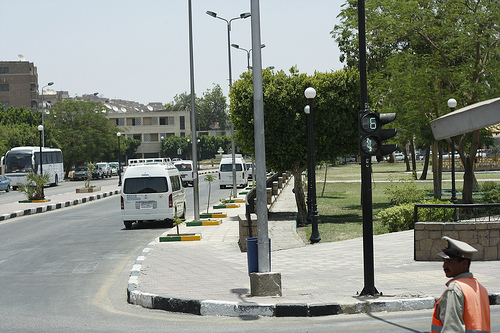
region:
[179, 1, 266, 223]
Series of street lamps along road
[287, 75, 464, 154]
White and black street lamps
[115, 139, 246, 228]
Three white vans driving on road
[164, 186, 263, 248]
Small trees with green and yellow planters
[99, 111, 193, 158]
Beige office building surrounded by bushes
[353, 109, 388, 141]
Number 6 on crosswalk light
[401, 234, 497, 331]
Crossing guard with orange vest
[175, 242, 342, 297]
Beige brick sidewalk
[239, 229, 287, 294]
Blue trash bin near street lamp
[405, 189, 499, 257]
Stone and metal fence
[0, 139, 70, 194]
White bus on road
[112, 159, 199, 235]
White van on the road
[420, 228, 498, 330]
Man wearing an orange vest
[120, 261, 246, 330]
Black and white stripes on curb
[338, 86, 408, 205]
Black light and signal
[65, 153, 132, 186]
Cars parked on left side of the road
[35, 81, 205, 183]
Beige building in background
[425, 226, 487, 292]
Tan hat on man's head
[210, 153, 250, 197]
White van parked on right side of road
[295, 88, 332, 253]
Two black and white street lamps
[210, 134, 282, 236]
a pole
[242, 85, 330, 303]
a pole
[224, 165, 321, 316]
a pole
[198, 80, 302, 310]
a pole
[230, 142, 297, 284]
a pole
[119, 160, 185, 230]
a large white van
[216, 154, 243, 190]
a large white van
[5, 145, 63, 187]
a white public service bus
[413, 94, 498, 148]
a security camera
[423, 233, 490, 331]
a police officer in vest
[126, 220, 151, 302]
a white striped curb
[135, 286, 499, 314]
a black and white striped curb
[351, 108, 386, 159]
an electric pedestrian crossing sign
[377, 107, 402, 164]
an electric traffic signal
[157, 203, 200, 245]
a green and yellow sidewalk planter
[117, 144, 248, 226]
white vans with raised roofs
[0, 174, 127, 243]
roadside curbs painted in stripes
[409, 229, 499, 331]
a crossing guard with orange vest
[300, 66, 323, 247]
white globed lights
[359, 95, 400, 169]
traffic light with timet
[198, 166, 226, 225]
a young sapling tree on walkway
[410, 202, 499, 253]
metal rail on low stone wall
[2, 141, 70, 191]
a public transit commuter bus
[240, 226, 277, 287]
blue trash receptacle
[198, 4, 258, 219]
double lamp street lights